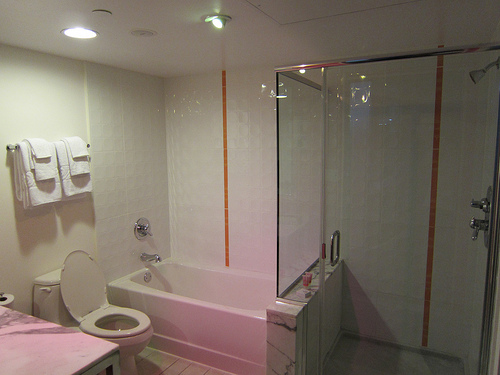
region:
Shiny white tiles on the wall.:
[85, 46, 498, 374]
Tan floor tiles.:
[120, 333, 471, 373]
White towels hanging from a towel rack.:
[5, 138, 91, 210]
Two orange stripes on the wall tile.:
[220, 51, 445, 352]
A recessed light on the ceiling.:
[60, 27, 100, 41]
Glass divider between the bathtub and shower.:
[275, 60, 325, 295]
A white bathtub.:
[105, 257, 300, 372]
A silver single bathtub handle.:
[130, 217, 156, 239]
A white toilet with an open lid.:
[30, 250, 150, 374]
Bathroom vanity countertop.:
[1, 304, 118, 374]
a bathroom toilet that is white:
[46, 230, 194, 366]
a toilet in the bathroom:
[71, 237, 181, 373]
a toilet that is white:
[9, 228, 176, 365]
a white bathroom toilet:
[49, 220, 234, 341]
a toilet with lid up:
[0, 226, 183, 369]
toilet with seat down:
[48, 226, 230, 365]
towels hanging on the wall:
[4, 109, 140, 221]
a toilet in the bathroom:
[29, 181, 254, 364]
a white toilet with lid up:
[24, 233, 269, 372]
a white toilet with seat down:
[48, 248, 255, 373]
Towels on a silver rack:
[6, 136, 95, 213]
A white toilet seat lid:
[58, 248, 108, 324]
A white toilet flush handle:
[37, 284, 52, 294]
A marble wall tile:
[264, 308, 299, 374]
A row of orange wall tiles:
[219, 66, 230, 268]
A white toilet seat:
[77, 304, 151, 340]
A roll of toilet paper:
[1, 291, 17, 315]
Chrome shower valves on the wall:
[464, 179, 499, 250]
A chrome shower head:
[462, 56, 499, 84]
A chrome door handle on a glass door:
[328, 229, 341, 269]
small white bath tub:
[107, 215, 275, 371]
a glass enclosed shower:
[272, 40, 497, 371]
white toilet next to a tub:
[35, 248, 152, 371]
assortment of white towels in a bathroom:
[7, 130, 89, 210]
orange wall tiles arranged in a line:
[220, 65, 225, 265]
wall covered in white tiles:
[160, 80, 222, 260]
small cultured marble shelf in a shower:
[276, 250, 341, 305]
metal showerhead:
[465, 47, 495, 93]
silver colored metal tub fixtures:
[126, 215, 166, 281]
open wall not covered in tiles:
[11, 53, 81, 126]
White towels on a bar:
[5, 132, 94, 214]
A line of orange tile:
[218, 65, 232, 267]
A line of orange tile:
[417, 43, 445, 350]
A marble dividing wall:
[262, 252, 347, 374]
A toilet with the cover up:
[58, 247, 115, 324]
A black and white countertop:
[0, 302, 120, 373]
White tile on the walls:
[80, 46, 498, 359]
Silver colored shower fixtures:
[466, 181, 497, 250]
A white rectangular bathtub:
[103, 253, 280, 373]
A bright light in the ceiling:
[56, 22, 98, 40]